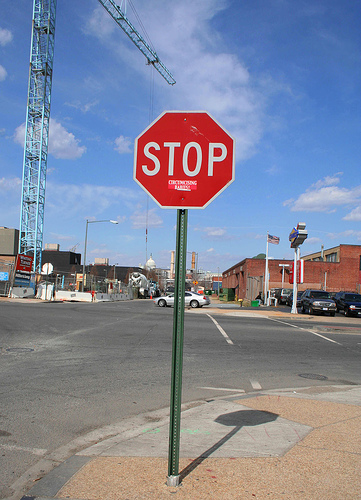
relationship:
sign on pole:
[133, 110, 236, 210] [166, 208, 187, 487]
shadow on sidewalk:
[180, 409, 279, 484] [24, 384, 360, 496]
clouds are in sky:
[2, 0, 359, 258] [1, 2, 358, 274]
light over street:
[81, 218, 120, 290] [2, 294, 360, 499]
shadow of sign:
[180, 409, 279, 484] [133, 110, 236, 210]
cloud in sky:
[14, 117, 85, 162] [1, 2, 358, 274]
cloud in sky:
[279, 176, 359, 225] [1, 2, 358, 274]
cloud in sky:
[82, 1, 294, 167] [1, 2, 358, 274]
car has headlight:
[336, 292, 359, 319] [349, 304, 354, 309]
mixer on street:
[127, 272, 151, 297] [2, 294, 360, 499]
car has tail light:
[153, 291, 209, 309] [202, 296, 208, 302]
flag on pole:
[268, 234, 281, 245] [264, 233, 270, 306]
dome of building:
[144, 254, 157, 267] [142, 255, 159, 272]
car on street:
[153, 291, 209, 309] [2, 294, 360, 499]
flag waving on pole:
[268, 234, 281, 245] [264, 233, 270, 306]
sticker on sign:
[168, 179, 198, 193] [133, 110, 236, 210]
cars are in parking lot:
[263, 287, 360, 317] [256, 299, 360, 324]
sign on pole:
[288, 225, 307, 246] [288, 248, 298, 315]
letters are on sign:
[141, 141, 225, 178] [133, 110, 236, 210]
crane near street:
[17, 2, 175, 283] [2, 294, 360, 499]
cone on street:
[148, 292, 156, 302] [2, 294, 360, 499]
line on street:
[203, 311, 232, 346] [2, 294, 360, 499]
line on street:
[262, 312, 342, 344] [2, 294, 360, 499]